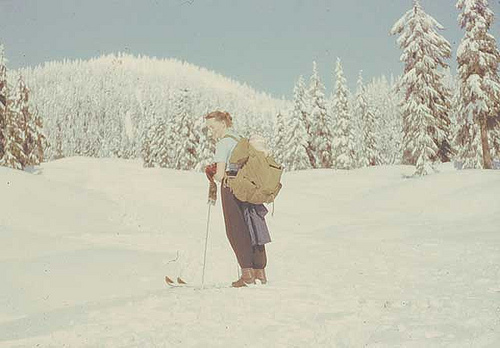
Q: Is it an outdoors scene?
A: Yes, it is outdoors.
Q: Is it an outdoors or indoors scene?
A: It is outdoors.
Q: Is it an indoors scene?
A: No, it is outdoors.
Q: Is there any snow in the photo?
A: Yes, there is snow.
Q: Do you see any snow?
A: Yes, there is snow.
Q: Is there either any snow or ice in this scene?
A: Yes, there is snow.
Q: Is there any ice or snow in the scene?
A: Yes, there is snow.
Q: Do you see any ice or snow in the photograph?
A: Yes, there is snow.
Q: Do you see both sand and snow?
A: No, there is snow but no sand.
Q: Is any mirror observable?
A: No, there are no mirrors.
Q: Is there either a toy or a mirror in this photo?
A: No, there are no mirrors or toys.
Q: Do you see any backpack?
A: Yes, there is a backpack.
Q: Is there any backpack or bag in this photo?
A: Yes, there is a backpack.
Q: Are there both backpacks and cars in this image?
A: No, there is a backpack but no cars.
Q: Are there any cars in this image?
A: No, there are no cars.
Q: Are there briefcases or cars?
A: No, there are no cars or briefcases.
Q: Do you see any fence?
A: No, there are no fences.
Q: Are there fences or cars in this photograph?
A: No, there are no fences or cars.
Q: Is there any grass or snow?
A: Yes, there is snow.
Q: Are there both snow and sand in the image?
A: No, there is snow but no sand.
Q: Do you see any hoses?
A: No, there are no hoses.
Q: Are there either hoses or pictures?
A: No, there are no hoses or pictures.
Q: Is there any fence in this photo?
A: No, there are no fences.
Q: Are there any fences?
A: No, there are no fences.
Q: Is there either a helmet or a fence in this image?
A: No, there are no fences or helmets.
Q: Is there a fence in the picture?
A: No, there are no fences.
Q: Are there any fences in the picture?
A: No, there are no fences.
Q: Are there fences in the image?
A: No, there are no fences.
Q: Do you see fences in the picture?
A: No, there are no fences.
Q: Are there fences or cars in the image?
A: No, there are no fences or cars.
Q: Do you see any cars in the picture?
A: No, there are no cars.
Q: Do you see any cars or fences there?
A: No, there are no cars or fences.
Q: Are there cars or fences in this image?
A: No, there are no cars or fences.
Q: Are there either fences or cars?
A: No, there are no cars or fences.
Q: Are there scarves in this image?
A: Yes, there is a scarf.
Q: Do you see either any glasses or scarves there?
A: Yes, there is a scarf.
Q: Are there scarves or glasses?
A: Yes, there is a scarf.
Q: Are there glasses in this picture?
A: No, there are no glasses.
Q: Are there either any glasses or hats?
A: No, there are no glasses or hats.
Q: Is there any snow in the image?
A: Yes, there is snow.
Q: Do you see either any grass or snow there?
A: Yes, there is snow.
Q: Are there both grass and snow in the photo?
A: No, there is snow but no grass.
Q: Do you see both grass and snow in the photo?
A: No, there is snow but no grass.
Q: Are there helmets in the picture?
A: No, there are no helmets.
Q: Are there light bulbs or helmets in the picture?
A: No, there are no helmets or light bulbs.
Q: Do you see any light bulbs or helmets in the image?
A: No, there are no helmets or light bulbs.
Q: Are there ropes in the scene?
A: No, there are no ropes.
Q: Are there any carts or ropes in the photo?
A: No, there are no ropes or carts.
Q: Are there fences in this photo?
A: No, there are no fences.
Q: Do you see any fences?
A: No, there are no fences.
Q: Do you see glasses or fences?
A: No, there are no fences or glasses.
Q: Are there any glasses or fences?
A: No, there are no fences or glasses.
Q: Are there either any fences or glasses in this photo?
A: No, there are no fences or glasses.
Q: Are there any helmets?
A: No, there are no helmets.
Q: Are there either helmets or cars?
A: No, there are no helmets or cars.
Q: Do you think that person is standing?
A: Yes, the person is standing.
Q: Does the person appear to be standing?
A: Yes, the person is standing.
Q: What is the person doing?
A: The person is standing.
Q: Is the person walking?
A: No, the person is standing.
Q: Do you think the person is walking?
A: No, the person is standing.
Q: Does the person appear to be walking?
A: No, the person is standing.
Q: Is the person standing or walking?
A: The person is standing.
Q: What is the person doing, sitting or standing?
A: The person is standing.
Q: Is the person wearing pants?
A: Yes, the person is wearing pants.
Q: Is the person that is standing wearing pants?
A: Yes, the person is wearing pants.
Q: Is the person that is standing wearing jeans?
A: No, the person is wearing pants.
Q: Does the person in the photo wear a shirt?
A: Yes, the person wears a shirt.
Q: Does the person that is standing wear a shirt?
A: Yes, the person wears a shirt.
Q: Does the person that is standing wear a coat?
A: No, the person wears a shirt.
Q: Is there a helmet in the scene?
A: No, there are no helmets.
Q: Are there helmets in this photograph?
A: No, there are no helmets.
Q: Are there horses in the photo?
A: No, there are no horses.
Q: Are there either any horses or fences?
A: No, there are no horses or fences.